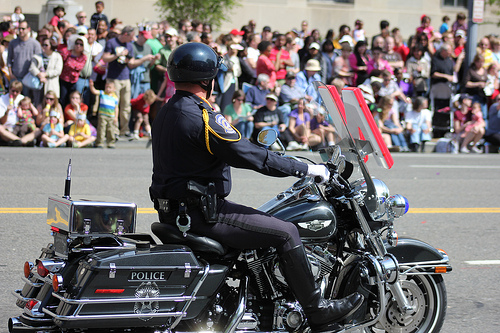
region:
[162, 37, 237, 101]
the head of a man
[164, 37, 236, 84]
a black helmet on the man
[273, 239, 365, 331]
a black boot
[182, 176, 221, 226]
a gun in the holster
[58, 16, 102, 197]
a silver antenna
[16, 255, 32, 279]
a turn signal on the motorcycle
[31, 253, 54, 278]
a red rear light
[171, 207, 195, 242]
a pair of metal handcuffs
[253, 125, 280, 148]
a rear view mirror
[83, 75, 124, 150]
a boy on the street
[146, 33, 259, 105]
Black helmet on a man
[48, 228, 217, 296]
Police, written on a motorcycle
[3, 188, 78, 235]
Yellow line on a road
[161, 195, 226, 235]
Handcuffs on a belt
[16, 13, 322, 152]
Crowd by a road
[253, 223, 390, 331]
Black boots on a man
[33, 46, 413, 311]
Man on a motorcycle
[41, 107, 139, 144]
People sitting by a road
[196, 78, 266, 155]
Emblem on a sleeve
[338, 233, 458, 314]
Tire on a motorcycle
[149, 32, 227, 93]
The police officer is wearing a helmet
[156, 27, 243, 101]
The police officer is wearing a black helmet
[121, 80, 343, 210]
The police officer is wearing a coat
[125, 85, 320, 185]
The police officer is wearing a black coat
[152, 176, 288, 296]
The police officer is wearing pants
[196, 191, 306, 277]
The police officer is wearing black pants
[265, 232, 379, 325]
The police officer is wearing boots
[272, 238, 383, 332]
The police officer is wearing black boots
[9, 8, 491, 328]
The picture has multiple colors in it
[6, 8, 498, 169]
The picture has people in the background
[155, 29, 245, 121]
black motorcycle helmet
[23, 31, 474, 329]
police officer riding motorcycle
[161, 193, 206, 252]
silver metal handcuffs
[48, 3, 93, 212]
radio antenna on back of motorcycle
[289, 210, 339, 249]
Harley Davidson motorcycle logo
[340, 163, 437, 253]
blue light on front of police motorcycle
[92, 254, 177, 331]
police logo on back of motorcycle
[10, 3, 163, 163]
crowd standing on street corner watching parade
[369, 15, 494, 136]
crowd standing on street coroner watching parade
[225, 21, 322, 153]
crowd standing on street coroner watching parade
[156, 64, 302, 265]
A policeman on a motorcycle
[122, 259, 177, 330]
Police label on the side of a motorcycle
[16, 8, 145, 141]
A crowd lined up on the side of a road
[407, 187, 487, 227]
A yellow stripe dividing lanes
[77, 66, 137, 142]
A little boy with his hand held up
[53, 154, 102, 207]
An antenna on the back of a motorcycle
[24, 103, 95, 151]
Children seated on the ground watching a parade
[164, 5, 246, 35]
A tree behind the crowd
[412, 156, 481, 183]
A white line in the road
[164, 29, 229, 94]
A black helmet on a policeman's head